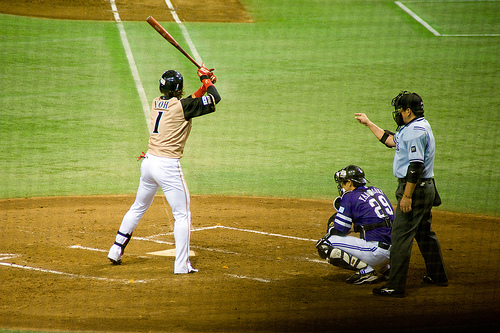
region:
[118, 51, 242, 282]
player on home plate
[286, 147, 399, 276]
catcher in front of umpire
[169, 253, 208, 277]
foot of the player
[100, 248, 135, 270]
foot of the player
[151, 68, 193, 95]
helmet on player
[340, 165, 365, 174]
helmet on player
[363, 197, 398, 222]
number on back of jersey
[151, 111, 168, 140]
number on back of jersey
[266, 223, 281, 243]
white chalk on ground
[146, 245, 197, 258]
home plate base on ground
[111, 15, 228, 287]
baseball player at the plate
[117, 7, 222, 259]
baseball player holding a bat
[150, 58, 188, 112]
baseball player wearing a helmet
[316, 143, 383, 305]
baseball catcher behind the plate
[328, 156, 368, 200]
baseball catcher wearing face mask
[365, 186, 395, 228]
number on baseball player's back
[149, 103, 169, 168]
number on baseball player's back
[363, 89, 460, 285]
baseball umpire standing behind the catcher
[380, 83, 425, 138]
face mask on the umpire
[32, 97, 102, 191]
grass on the infield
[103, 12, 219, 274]
hitter with bat held over head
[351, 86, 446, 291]
umpire standing and pointing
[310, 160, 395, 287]
catcher crouched down on brown ground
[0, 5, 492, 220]
green grass in back of players and umpire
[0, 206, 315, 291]
white lines around batter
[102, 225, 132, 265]
straps and pad on lower leg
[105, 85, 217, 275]
tan and black shirt over white pants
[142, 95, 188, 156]
surname and number on back of shirt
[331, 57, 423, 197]
face masks on catcher and umpire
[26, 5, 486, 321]
faint black lines of net in front of players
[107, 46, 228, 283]
A baseball player at bat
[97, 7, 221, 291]
Baseball player with a red bat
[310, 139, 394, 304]
Pitcher is wearing purple and gray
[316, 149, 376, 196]
The catcher is wearing a mask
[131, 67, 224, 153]
The batter is wearing a beige and black jersey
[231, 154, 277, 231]
The turf is natural and real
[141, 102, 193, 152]
The number one is on the batters back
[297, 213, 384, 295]
The catcher has shin guards om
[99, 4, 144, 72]
White stripes painted on the field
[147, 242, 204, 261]
Home plate is in the dirt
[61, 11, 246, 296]
baseball player standing at home plate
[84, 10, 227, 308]
player wearing red gloves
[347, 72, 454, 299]
umpire pointing toward pitcher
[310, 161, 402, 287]
catcher wearing protective gear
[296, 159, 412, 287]
catcher wearing purple jersey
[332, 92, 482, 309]
umpire wearing blue shirt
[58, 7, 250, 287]
batter using red bat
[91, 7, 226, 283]
player wearing number 1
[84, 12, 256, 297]
batter in hitting stance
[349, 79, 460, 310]
umpire wearing black shoes